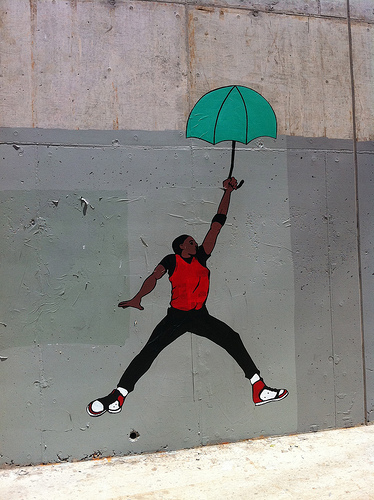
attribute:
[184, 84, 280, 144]
umbrella — green 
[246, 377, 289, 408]
shoe — red and white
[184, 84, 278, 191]
umbrella — drawing, green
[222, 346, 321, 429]
shoe — red, white, black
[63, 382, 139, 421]
shoe — black, red, white